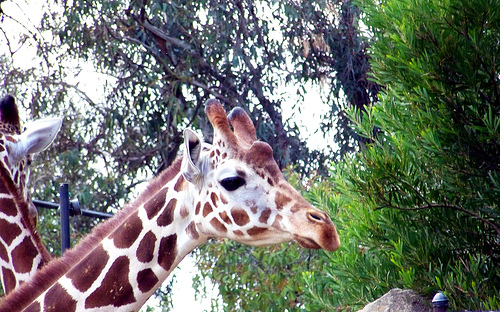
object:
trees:
[341, 0, 500, 287]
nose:
[304, 207, 337, 229]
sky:
[1, 0, 409, 196]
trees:
[118, 2, 295, 168]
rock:
[357, 281, 457, 311]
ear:
[24, 116, 68, 154]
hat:
[429, 291, 453, 307]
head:
[427, 293, 449, 310]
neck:
[0, 179, 208, 310]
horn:
[201, 96, 241, 148]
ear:
[182, 125, 210, 181]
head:
[169, 96, 346, 252]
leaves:
[438, 126, 462, 137]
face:
[217, 137, 336, 244]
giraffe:
[0, 96, 343, 311]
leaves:
[397, 138, 422, 152]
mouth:
[285, 229, 342, 253]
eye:
[218, 175, 249, 194]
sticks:
[381, 200, 500, 235]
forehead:
[241, 139, 283, 178]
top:
[428, 290, 452, 304]